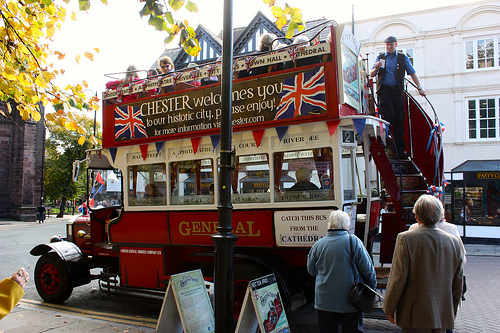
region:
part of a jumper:
[316, 283, 338, 312]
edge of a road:
[91, 308, 104, 319]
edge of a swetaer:
[324, 298, 347, 314]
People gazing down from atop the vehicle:
[125, 40, 330, 90]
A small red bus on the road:
[72, 45, 436, 314]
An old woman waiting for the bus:
[310, 207, 377, 327]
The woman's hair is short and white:
[320, 206, 357, 224]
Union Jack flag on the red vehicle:
[278, 70, 329, 118]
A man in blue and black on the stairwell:
[377, 36, 419, 149]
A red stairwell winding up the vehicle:
[365, 83, 457, 275]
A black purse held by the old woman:
[351, 278, 378, 319]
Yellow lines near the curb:
[22, 299, 149, 326]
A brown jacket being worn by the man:
[390, 233, 462, 318]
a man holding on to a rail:
[366, 32, 428, 159]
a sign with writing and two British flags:
[113, 65, 327, 142]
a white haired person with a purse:
[301, 209, 378, 330]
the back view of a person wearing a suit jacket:
[379, 193, 466, 331]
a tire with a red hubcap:
[32, 250, 71, 303]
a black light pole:
[214, 0, 238, 332]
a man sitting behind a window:
[271, 145, 334, 203]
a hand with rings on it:
[12, 265, 30, 288]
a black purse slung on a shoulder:
[346, 232, 378, 316]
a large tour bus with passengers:
[30, 25, 444, 310]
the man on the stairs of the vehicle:
[367, 34, 425, 157]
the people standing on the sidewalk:
[306, 193, 461, 331]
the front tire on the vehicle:
[33, 255, 75, 303]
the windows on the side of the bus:
[125, 144, 335, 201]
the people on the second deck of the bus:
[102, 22, 334, 94]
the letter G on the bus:
[178, 220, 192, 235]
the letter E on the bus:
[190, 220, 200, 233]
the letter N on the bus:
[200, 220, 211, 233]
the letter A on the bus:
[234, 220, 245, 232]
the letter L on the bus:
[245, 218, 261, 236]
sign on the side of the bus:
[110, 67, 339, 142]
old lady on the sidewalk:
[301, 203, 383, 331]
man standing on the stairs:
[373, 38, 418, 139]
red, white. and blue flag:
[269, 66, 328, 119]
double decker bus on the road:
[14, 57, 463, 328]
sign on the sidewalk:
[228, 268, 303, 331]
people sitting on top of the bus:
[109, 21, 333, 81]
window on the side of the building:
[464, 98, 499, 139]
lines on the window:
[458, 34, 499, 66]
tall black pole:
[211, 4, 238, 330]